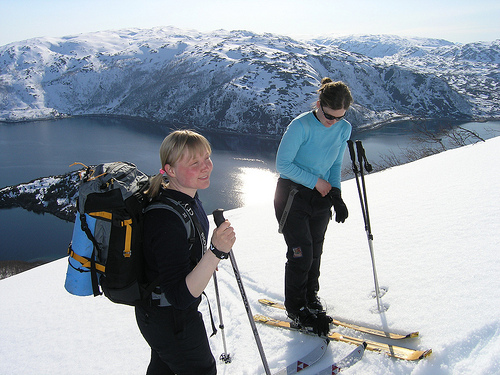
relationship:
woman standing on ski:
[272, 77, 353, 334] [249, 310, 433, 362]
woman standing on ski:
[272, 77, 353, 334] [256, 296, 420, 338]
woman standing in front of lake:
[131, 129, 234, 375] [5, 120, 497, 284]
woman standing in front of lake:
[272, 77, 353, 334] [5, 120, 497, 284]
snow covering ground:
[2, 157, 494, 359] [0, 131, 482, 372]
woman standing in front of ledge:
[131, 129, 234, 375] [0, 252, 70, 284]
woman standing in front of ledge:
[272, 77, 353, 334] [0, 252, 70, 284]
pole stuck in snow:
[357, 160, 380, 311] [6, 135, 496, 367]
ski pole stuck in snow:
[345, 140, 378, 293] [6, 135, 496, 367]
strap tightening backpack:
[85, 207, 134, 258] [64, 161, 148, 303]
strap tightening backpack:
[66, 242, 106, 272] [64, 161, 148, 303]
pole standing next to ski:
[357, 160, 380, 311] [249, 310, 433, 362]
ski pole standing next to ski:
[345, 140, 378, 293] [253, 292, 423, 341]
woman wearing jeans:
[272, 77, 353, 334] [253, 167, 357, 327]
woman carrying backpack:
[131, 129, 234, 375] [62, 158, 198, 307]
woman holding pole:
[131, 129, 234, 375] [228, 249, 271, 375]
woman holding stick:
[131, 129, 234, 375] [211, 255, 233, 365]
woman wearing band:
[131, 129, 234, 375] [156, 166, 166, 176]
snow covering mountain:
[1, 22, 483, 136] [0, 26, 499, 135]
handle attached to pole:
[211, 196, 251, 258] [228, 249, 271, 375]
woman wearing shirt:
[272, 77, 353, 334] [273, 110, 351, 190]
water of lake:
[94, 128, 141, 160] [3, 104, 499, 183]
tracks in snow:
[421, 311, 496, 371] [6, 135, 496, 367]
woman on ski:
[272, 77, 353, 335] [253, 292, 423, 341]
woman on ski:
[131, 129, 234, 375] [249, 305, 432, 360]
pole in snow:
[341, 145, 416, 371] [400, 184, 462, 269]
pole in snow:
[212, 214, 292, 371] [400, 184, 462, 269]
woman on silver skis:
[58, 135, 271, 373] [201, 202, 300, 374]